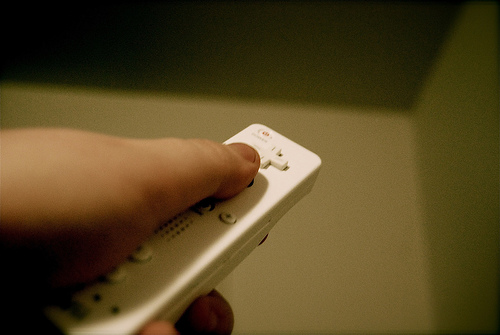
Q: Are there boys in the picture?
A: No, there are no boys.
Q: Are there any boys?
A: No, there are no boys.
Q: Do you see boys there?
A: No, there are no boys.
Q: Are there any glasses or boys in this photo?
A: No, there are no boys or glasses.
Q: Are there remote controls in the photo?
A: Yes, there is a remote control.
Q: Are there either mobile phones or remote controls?
A: Yes, there is a remote control.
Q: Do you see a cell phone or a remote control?
A: Yes, there is a remote control.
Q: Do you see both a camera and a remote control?
A: No, there is a remote control but no cameras.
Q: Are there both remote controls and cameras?
A: No, there is a remote control but no cameras.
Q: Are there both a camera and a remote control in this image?
A: No, there is a remote control but no cameras.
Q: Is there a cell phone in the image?
A: No, there are no cell phones.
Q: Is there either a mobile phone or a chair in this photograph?
A: No, there are no cell phones or chairs.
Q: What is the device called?
A: The device is a remote control.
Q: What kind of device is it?
A: The device is a remote control.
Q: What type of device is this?
A: This is a remote control.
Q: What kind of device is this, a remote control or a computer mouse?
A: This is a remote control.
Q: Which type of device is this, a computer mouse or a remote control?
A: This is a remote control.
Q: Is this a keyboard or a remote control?
A: This is a remote control.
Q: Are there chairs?
A: No, there are no chairs.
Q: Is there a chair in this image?
A: No, there are no chairs.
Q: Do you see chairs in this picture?
A: No, there are no chairs.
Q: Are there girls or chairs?
A: No, there are no chairs or girls.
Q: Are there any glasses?
A: No, there are no glasses.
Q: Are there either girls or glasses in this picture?
A: No, there are no glasses or girls.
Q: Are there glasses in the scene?
A: No, there are no glasses.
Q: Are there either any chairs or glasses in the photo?
A: No, there are no glasses or chairs.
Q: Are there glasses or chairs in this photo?
A: No, there are no glasses or chairs.